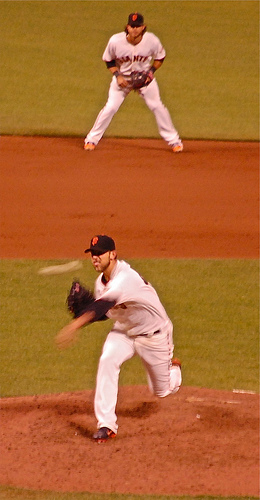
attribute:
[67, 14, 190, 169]
baseball player — behind, standing, leaning, playing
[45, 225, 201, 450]
baseball player — throwing, pitching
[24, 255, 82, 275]
ball — blurry, fast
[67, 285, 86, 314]
glove — black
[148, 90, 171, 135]
leg — wide, spread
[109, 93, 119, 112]
leg — wide, spread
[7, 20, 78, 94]
grass — green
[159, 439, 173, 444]
dirt — brown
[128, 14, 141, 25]
hat — black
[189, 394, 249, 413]
plate — white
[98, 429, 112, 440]
shoe — orange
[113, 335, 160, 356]
pants — white